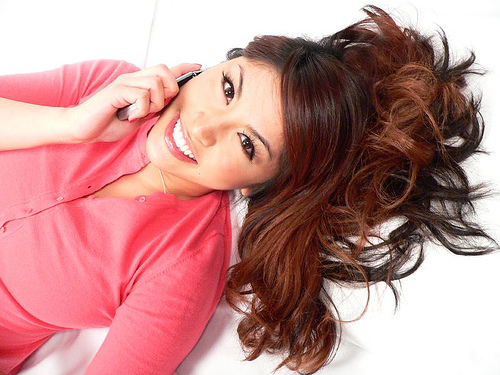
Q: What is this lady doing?
A: Talking on the phone.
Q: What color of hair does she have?
A: Brown.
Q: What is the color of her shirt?
A: Pink.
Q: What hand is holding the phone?
A: Right.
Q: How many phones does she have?
A: One.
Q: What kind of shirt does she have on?
A: Button up.